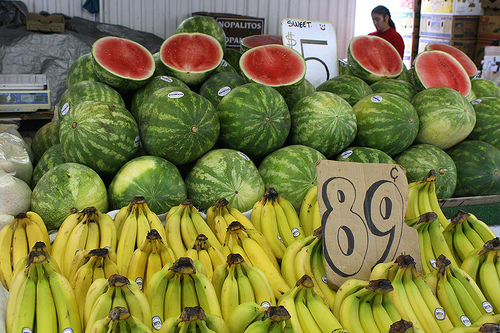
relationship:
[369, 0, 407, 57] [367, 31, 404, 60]
man wearing red shirt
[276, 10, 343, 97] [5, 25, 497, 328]
sign on fruit stand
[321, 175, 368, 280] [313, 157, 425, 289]
number on cardboard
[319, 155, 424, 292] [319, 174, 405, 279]
sign shows 89 cents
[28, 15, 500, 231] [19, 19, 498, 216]
watermelon in pile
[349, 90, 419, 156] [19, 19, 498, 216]
watermelon in pile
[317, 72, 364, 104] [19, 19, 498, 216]
watermelon in pile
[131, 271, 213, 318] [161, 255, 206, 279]
banana has end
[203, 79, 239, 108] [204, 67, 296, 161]
sticker on water melon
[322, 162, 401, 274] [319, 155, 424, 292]
89 cents painted on sign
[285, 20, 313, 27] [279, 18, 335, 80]
sweet written on sign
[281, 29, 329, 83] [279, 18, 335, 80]
$5 written on sign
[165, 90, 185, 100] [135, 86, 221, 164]
sticker on watermelon